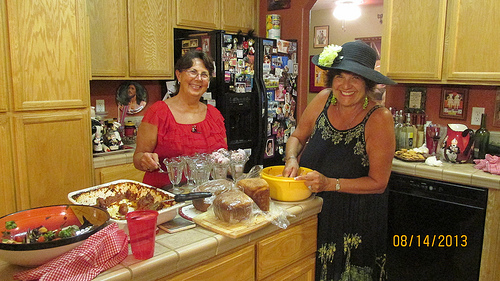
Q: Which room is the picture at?
A: It is at the kitchen.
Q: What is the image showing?
A: It is showing a kitchen.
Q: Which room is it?
A: It is a kitchen.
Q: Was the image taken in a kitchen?
A: Yes, it was taken in a kitchen.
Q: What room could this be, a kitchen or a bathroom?
A: It is a kitchen.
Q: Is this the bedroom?
A: No, it is the kitchen.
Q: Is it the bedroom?
A: No, it is the kitchen.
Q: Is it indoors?
A: Yes, it is indoors.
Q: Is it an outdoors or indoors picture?
A: It is indoors.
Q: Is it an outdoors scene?
A: No, it is indoors.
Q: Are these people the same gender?
A: Yes, all the people are female.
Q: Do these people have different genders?
A: No, all the people are female.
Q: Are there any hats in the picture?
A: Yes, there is a hat.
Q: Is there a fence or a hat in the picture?
A: Yes, there is a hat.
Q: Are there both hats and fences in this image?
A: No, there is a hat but no fences.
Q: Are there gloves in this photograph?
A: No, there are no gloves.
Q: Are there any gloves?
A: No, there are no gloves.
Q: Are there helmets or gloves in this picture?
A: No, there are no gloves or helmets.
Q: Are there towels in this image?
A: Yes, there is a towel.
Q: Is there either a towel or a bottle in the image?
A: Yes, there is a towel.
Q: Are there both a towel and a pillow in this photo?
A: No, there is a towel but no pillows.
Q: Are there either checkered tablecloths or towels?
A: Yes, there is a checkered towel.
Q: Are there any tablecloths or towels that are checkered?
A: Yes, the towel is checkered.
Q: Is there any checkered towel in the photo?
A: Yes, there is a checkered towel.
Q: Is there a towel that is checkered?
A: Yes, there is a towel that is checkered.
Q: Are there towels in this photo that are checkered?
A: Yes, there is a towel that is checkered.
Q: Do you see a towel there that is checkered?
A: Yes, there is a towel that is checkered.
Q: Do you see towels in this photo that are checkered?
A: Yes, there is a towel that is checkered.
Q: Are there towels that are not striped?
A: Yes, there is a checkered towel.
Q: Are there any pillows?
A: No, there are no pillows.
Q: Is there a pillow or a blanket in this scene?
A: No, there are no pillows or blankets.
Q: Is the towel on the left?
A: Yes, the towel is on the left of the image.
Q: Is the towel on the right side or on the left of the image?
A: The towel is on the left of the image.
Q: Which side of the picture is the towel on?
A: The towel is on the left of the image.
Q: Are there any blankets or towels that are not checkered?
A: No, there is a towel but it is checkered.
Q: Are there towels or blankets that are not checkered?
A: No, there is a towel but it is checkered.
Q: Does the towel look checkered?
A: Yes, the towel is checkered.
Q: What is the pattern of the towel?
A: The towel is checkered.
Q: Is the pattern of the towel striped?
A: No, the towel is checkered.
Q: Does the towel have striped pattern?
A: No, the towel is checkered.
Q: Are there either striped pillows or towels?
A: No, there is a towel but it is checkered.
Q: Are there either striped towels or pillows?
A: No, there is a towel but it is checkered.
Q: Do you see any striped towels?
A: No, there is a towel but it is checkered.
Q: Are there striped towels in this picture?
A: No, there is a towel but it is checkered.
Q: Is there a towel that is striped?
A: No, there is a towel but it is checkered.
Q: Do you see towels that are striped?
A: No, there is a towel but it is checkered.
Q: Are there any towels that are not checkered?
A: No, there is a towel but it is checkered.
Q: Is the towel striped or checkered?
A: The towel is checkered.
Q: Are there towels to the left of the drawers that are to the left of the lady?
A: Yes, there is a towel to the left of the drawers.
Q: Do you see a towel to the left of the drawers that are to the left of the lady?
A: Yes, there is a towel to the left of the drawers.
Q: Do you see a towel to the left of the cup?
A: Yes, there is a towel to the left of the cup.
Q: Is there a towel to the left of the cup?
A: Yes, there is a towel to the left of the cup.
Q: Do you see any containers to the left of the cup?
A: No, there is a towel to the left of the cup.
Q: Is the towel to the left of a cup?
A: Yes, the towel is to the left of a cup.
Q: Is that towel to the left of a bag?
A: No, the towel is to the left of a cup.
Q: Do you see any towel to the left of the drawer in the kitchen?
A: Yes, there is a towel to the left of the drawer.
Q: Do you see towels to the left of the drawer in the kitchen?
A: Yes, there is a towel to the left of the drawer.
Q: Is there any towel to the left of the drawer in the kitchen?
A: Yes, there is a towel to the left of the drawer.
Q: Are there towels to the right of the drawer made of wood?
A: No, the towel is to the left of the drawer.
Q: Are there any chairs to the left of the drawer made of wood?
A: No, there is a towel to the left of the drawer.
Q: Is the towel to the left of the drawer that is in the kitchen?
A: Yes, the towel is to the left of the drawer.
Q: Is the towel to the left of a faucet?
A: No, the towel is to the left of the drawer.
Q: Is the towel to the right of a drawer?
A: No, the towel is to the left of a drawer.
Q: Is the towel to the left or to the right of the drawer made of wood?
A: The towel is to the left of the drawer.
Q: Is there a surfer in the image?
A: No, there are no surfers.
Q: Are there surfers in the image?
A: No, there are no surfers.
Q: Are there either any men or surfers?
A: No, there are no surfers or men.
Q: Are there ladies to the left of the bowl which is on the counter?
A: Yes, there is a lady to the left of the bowl.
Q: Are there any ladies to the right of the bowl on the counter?
A: No, the lady is to the left of the bowl.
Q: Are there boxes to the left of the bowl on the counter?
A: No, there is a lady to the left of the bowl.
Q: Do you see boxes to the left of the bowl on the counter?
A: No, there is a lady to the left of the bowl.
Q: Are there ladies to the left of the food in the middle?
A: Yes, there is a lady to the left of the food.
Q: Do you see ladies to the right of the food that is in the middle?
A: No, the lady is to the left of the food.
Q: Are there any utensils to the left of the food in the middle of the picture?
A: No, there is a lady to the left of the food.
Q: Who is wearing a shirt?
A: The lady is wearing a shirt.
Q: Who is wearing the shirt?
A: The lady is wearing a shirt.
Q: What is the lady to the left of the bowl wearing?
A: The lady is wearing a shirt.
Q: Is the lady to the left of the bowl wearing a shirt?
A: Yes, the lady is wearing a shirt.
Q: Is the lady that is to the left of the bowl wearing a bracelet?
A: No, the lady is wearing a shirt.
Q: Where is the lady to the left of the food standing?
A: The lady is standing in the kitchen.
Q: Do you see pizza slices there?
A: No, there are no pizza slices.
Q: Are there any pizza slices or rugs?
A: No, there are no pizza slices or rugs.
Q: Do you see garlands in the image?
A: No, there are no garlands.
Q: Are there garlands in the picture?
A: No, there are no garlands.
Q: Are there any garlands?
A: No, there are no garlands.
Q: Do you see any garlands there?
A: No, there are no garlands.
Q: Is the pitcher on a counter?
A: Yes, the pitcher is on a counter.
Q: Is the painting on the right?
A: Yes, the painting is on the right of the image.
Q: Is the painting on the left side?
A: No, the painting is on the right of the image.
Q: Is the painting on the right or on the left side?
A: The painting is on the right of the image.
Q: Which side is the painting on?
A: The painting is on the right of the image.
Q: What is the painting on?
A: The painting is on the wall.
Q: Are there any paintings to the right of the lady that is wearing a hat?
A: Yes, there is a painting to the right of the lady.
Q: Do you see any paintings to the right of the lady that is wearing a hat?
A: Yes, there is a painting to the right of the lady.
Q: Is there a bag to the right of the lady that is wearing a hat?
A: No, there is a painting to the right of the lady.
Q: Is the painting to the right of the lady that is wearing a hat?
A: Yes, the painting is to the right of the lady.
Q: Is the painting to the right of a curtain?
A: No, the painting is to the right of the lady.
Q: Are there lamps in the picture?
A: No, there are no lamps.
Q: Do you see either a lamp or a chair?
A: No, there are no lamps or chairs.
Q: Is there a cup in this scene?
A: Yes, there is a cup.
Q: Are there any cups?
A: Yes, there is a cup.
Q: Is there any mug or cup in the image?
A: Yes, there is a cup.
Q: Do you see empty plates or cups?
A: Yes, there is an empty cup.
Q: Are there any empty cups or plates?
A: Yes, there is an empty cup.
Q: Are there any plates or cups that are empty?
A: Yes, the cup is empty.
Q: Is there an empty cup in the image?
A: Yes, there is an empty cup.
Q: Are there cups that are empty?
A: Yes, there is a cup that is empty.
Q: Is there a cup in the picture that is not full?
A: Yes, there is a empty cup.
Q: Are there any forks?
A: No, there are no forks.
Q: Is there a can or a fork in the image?
A: No, there are no forks or cans.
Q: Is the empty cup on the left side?
A: Yes, the cup is on the left of the image.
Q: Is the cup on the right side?
A: No, the cup is on the left of the image.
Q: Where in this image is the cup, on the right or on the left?
A: The cup is on the left of the image.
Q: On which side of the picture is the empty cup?
A: The cup is on the left of the image.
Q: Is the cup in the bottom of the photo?
A: Yes, the cup is in the bottom of the image.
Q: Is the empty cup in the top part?
A: No, the cup is in the bottom of the image.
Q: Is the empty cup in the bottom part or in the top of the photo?
A: The cup is in the bottom of the image.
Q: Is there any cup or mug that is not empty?
A: No, there is a cup but it is empty.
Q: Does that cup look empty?
A: Yes, the cup is empty.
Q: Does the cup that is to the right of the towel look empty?
A: Yes, the cup is empty.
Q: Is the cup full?
A: No, the cup is empty.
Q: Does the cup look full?
A: No, the cup is empty.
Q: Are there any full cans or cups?
A: No, there is a cup but it is empty.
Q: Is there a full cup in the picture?
A: No, there is a cup but it is empty.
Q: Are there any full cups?
A: No, there is a cup but it is empty.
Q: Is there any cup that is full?
A: No, there is a cup but it is empty.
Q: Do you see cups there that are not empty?
A: No, there is a cup but it is empty.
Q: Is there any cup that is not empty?
A: No, there is a cup but it is empty.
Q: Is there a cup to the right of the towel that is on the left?
A: Yes, there is a cup to the right of the towel.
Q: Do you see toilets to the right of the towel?
A: No, there is a cup to the right of the towel.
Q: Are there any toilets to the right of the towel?
A: No, there is a cup to the right of the towel.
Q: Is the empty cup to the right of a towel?
A: Yes, the cup is to the right of a towel.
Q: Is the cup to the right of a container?
A: No, the cup is to the right of a towel.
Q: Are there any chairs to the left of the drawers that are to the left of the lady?
A: No, there is a cup to the left of the drawers.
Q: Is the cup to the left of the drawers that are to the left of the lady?
A: Yes, the cup is to the left of the drawers.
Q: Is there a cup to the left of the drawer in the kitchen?
A: Yes, there is a cup to the left of the drawer.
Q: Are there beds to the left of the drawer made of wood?
A: No, there is a cup to the left of the drawer.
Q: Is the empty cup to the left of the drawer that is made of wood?
A: Yes, the cup is to the left of the drawer.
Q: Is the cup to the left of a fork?
A: No, the cup is to the left of the drawer.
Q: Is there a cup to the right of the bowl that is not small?
A: Yes, there is a cup to the right of the bowl.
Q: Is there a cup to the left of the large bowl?
A: No, the cup is to the right of the bowl.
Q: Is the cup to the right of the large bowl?
A: Yes, the cup is to the right of the bowl.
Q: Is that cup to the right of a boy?
A: No, the cup is to the right of the bowl.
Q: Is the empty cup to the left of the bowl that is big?
A: No, the cup is to the right of the bowl.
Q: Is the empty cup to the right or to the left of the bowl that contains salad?
A: The cup is to the right of the bowl.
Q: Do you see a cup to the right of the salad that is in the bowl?
A: Yes, there is a cup to the right of the salad.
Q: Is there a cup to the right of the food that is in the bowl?
A: Yes, there is a cup to the right of the salad.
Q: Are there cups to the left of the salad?
A: No, the cup is to the right of the salad.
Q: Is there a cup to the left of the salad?
A: No, the cup is to the right of the salad.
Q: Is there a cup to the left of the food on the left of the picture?
A: No, the cup is to the right of the salad.